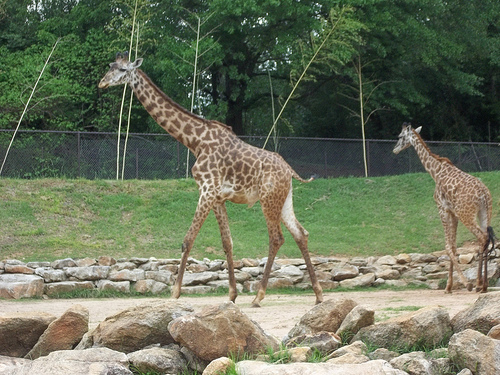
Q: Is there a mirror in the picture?
A: No, there are no mirrors.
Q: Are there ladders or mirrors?
A: No, there are no mirrors or ladders.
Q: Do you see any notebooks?
A: No, there are no notebooks.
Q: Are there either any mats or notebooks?
A: No, there are no notebooks or mats.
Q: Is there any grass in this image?
A: Yes, there is grass.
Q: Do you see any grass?
A: Yes, there is grass.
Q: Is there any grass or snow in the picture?
A: Yes, there is grass.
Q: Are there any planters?
A: No, there are no planters.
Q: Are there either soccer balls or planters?
A: No, there are no planters or soccer balls.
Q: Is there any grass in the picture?
A: Yes, there is grass.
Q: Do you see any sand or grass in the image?
A: Yes, there is grass.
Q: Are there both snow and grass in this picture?
A: No, there is grass but no snow.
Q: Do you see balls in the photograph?
A: No, there are no balls.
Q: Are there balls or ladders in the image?
A: No, there are no balls or ladders.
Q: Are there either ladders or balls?
A: No, there are no balls or ladders.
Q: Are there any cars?
A: No, there are no cars.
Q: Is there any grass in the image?
A: Yes, there is grass.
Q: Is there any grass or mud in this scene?
A: Yes, there is grass.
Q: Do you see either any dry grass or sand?
A: Yes, there is dry grass.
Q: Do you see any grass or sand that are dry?
A: Yes, the grass is dry.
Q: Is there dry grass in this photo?
A: Yes, there is dry grass.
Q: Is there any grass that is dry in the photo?
A: Yes, there is dry grass.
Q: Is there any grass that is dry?
A: Yes, there is grass that is dry.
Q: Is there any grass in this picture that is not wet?
A: Yes, there is dry grass.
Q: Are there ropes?
A: No, there are no ropes.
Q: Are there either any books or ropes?
A: No, there are no ropes or books.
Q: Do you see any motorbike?
A: No, there are no motorcycles.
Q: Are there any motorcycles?
A: No, there are no motorcycles.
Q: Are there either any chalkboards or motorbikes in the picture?
A: No, there are no motorbikes or chalkboards.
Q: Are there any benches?
A: No, there are no benches.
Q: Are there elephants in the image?
A: No, there are no elephants.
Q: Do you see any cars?
A: No, there are no cars.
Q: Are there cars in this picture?
A: No, there are no cars.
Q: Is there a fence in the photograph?
A: Yes, there is a fence.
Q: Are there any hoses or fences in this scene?
A: Yes, there is a fence.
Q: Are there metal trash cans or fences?
A: Yes, there is a metal fence.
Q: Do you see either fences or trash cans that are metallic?
A: Yes, the fence is metallic.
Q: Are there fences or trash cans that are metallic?
A: Yes, the fence is metallic.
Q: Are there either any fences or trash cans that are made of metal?
A: Yes, the fence is made of metal.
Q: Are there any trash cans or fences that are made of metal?
A: Yes, the fence is made of metal.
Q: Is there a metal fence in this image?
A: Yes, there is a metal fence.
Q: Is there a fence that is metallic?
A: Yes, there is a fence that is metallic.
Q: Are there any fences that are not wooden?
A: Yes, there is a metallic fence.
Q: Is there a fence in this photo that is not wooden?
A: Yes, there is a metallic fence.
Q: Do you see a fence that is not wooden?
A: Yes, there is a metallic fence.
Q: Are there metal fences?
A: Yes, there is a fence that is made of metal.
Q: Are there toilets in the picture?
A: No, there are no toilets.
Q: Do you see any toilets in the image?
A: No, there are no toilets.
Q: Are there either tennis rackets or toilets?
A: No, there are no toilets or tennis rackets.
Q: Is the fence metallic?
A: Yes, the fence is metallic.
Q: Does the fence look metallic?
A: Yes, the fence is metallic.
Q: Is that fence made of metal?
A: Yes, the fence is made of metal.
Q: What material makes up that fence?
A: The fence is made of metal.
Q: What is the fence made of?
A: The fence is made of metal.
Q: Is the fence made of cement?
A: No, the fence is made of metal.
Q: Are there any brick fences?
A: No, there is a fence but it is made of metal.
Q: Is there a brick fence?
A: No, there is a fence but it is made of metal.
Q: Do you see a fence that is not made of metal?
A: No, there is a fence but it is made of metal.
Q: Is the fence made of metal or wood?
A: The fence is made of metal.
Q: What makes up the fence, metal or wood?
A: The fence is made of metal.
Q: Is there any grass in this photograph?
A: Yes, there is grass.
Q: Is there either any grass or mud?
A: Yes, there is grass.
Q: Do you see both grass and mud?
A: No, there is grass but no mud.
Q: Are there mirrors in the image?
A: No, there are no mirrors.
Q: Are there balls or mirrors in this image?
A: No, there are no mirrors or balls.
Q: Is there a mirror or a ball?
A: No, there are no mirrors or balls.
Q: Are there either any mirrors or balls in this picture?
A: No, there are no mirrors or balls.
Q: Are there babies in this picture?
A: Yes, there is a baby.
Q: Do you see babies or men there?
A: Yes, there is a baby.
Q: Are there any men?
A: No, there are no men.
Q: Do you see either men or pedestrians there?
A: No, there are no men or pedestrians.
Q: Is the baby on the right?
A: Yes, the baby is on the right of the image.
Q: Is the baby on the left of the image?
A: No, the baby is on the right of the image.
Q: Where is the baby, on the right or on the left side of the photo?
A: The baby is on the right of the image.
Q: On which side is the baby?
A: The baby is on the right of the image.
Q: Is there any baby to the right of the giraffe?
A: Yes, there is a baby to the right of the giraffe.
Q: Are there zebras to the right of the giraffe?
A: No, there is a baby to the right of the giraffe.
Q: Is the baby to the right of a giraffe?
A: Yes, the baby is to the right of a giraffe.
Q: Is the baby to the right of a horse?
A: No, the baby is to the right of a giraffe.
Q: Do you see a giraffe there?
A: Yes, there is a giraffe.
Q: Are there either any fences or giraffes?
A: Yes, there is a giraffe.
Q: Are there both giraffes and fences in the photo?
A: Yes, there are both a giraffe and a fence.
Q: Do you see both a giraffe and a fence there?
A: Yes, there are both a giraffe and a fence.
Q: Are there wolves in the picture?
A: No, there are no wolves.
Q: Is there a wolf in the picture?
A: No, there are no wolves.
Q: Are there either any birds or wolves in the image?
A: No, there are no wolves or birds.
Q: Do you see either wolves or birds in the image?
A: No, there are no wolves or birds.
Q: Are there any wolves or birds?
A: No, there are no wolves or birds.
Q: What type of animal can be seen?
A: The animal is a giraffe.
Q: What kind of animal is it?
A: The animal is a giraffe.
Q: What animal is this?
A: This is a giraffe.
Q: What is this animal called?
A: This is a giraffe.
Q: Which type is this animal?
A: This is a giraffe.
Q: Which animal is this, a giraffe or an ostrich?
A: This is a giraffe.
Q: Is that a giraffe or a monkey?
A: That is a giraffe.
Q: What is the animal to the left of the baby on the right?
A: The animal is a giraffe.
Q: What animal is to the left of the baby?
A: The animal is a giraffe.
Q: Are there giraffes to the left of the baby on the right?
A: Yes, there is a giraffe to the left of the baby.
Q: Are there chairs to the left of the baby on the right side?
A: No, there is a giraffe to the left of the baby.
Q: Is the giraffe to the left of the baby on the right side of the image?
A: Yes, the giraffe is to the left of the baby.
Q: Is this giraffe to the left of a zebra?
A: No, the giraffe is to the left of the baby.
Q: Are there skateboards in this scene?
A: No, there are no skateboards.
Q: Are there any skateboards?
A: No, there are no skateboards.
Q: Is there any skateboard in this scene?
A: No, there are no skateboards.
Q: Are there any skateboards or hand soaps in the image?
A: No, there are no skateboards or hand soaps.